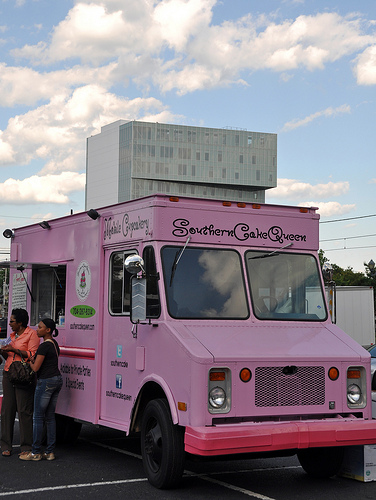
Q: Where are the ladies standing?
A: By the window.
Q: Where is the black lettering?
A: On the pink truck.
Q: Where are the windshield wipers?
A: On the windshield.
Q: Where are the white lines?
A: Painted on the street.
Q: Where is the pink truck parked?
A: On a street.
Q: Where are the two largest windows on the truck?
A: In the front.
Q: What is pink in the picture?
A: A truck.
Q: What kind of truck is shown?
A: Food truck.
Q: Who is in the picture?
A: Two women.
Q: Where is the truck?
A: Parking Lot.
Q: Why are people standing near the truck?
A: They are patrons.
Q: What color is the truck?
A: Pink.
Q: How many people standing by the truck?
A: Two.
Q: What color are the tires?
A: Black.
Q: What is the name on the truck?
A: Southern Cake Queen.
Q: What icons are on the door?
A: Twitter and Facebook.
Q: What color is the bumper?
A: Hot pink.